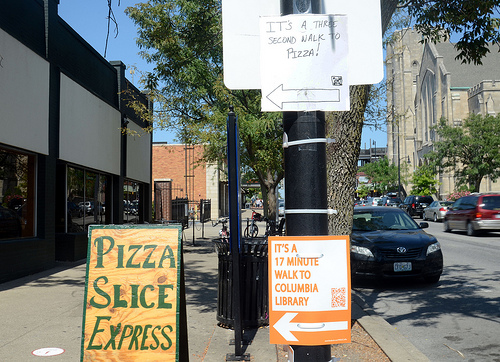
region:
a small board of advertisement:
[82, 217, 178, 354]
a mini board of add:
[261, 230, 379, 359]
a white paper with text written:
[248, 3, 387, 163]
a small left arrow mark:
[272, 304, 352, 346]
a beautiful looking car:
[329, 193, 464, 295]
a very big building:
[398, 48, 495, 198]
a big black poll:
[265, 5, 362, 360]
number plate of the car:
[383, 259, 423, 277]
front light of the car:
[354, 236, 387, 276]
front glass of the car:
[356, 200, 421, 241]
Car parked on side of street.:
[348, 201, 465, 293]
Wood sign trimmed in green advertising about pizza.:
[75, 218, 190, 358]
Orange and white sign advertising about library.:
[263, 226, 368, 356]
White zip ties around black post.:
[274, 128, 339, 226]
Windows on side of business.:
[6, 134, 161, 246]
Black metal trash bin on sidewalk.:
[214, 233, 271, 330]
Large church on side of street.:
[384, 31, 499, 197]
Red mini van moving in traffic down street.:
[445, 188, 498, 232]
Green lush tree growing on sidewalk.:
[133, 1, 484, 242]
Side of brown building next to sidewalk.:
[159, 138, 230, 228]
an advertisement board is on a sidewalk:
[82, 218, 187, 358]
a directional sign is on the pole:
[266, 230, 354, 352]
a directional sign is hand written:
[260, 13, 352, 114]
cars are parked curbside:
[346, 185, 498, 326]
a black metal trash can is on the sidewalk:
[211, 232, 272, 332]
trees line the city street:
[138, 5, 499, 319]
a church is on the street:
[384, 24, 498, 221]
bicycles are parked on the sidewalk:
[208, 204, 268, 249]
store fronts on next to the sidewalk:
[16, 35, 221, 356]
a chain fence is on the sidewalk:
[176, 206, 214, 251]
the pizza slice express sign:
[81, 220, 183, 360]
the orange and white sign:
[265, 231, 352, 346]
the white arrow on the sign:
[274, 312, 350, 344]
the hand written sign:
[256, 10, 351, 112]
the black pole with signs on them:
[269, 0, 336, 356]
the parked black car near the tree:
[351, 195, 438, 281]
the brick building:
[152, 142, 211, 211]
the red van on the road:
[441, 194, 498, 233]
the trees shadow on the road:
[427, 257, 498, 340]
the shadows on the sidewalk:
[180, 235, 214, 325]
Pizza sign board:
[79, 219, 179, 360]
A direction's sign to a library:
[259, 227, 358, 351]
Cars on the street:
[357, 175, 499, 302]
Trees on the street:
[385, 112, 496, 190]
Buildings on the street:
[10, 15, 211, 218]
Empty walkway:
[10, 274, 77, 358]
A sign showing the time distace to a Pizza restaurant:
[203, 4, 382, 118]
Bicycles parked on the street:
[209, 210, 262, 240]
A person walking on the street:
[186, 199, 201, 225]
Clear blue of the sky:
[81, 1, 135, 58]